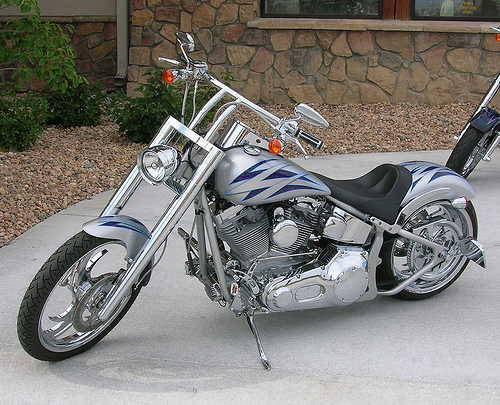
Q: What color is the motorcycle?
A: Gray.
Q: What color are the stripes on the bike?
A: Blue.